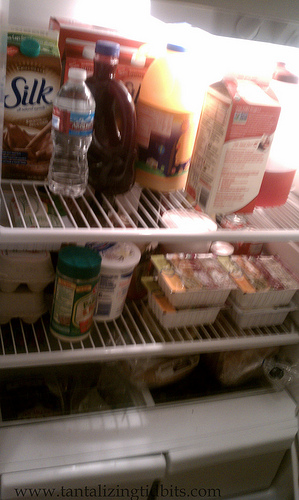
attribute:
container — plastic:
[101, 248, 146, 329]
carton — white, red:
[2, 23, 64, 185]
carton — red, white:
[165, 420, 298, 498]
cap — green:
[17, 36, 42, 57]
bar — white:
[1, 225, 297, 242]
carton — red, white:
[208, 74, 258, 217]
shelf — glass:
[1, 354, 276, 415]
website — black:
[12, 471, 246, 497]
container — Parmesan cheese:
[48, 245, 101, 342]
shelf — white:
[1, 169, 298, 244]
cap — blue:
[167, 44, 186, 50]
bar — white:
[2, 244, 288, 332]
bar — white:
[0, 332, 298, 367]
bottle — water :
[47, 64, 101, 201]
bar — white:
[5, 337, 273, 398]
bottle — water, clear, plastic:
[45, 65, 97, 198]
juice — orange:
[133, 38, 209, 196]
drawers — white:
[20, 406, 279, 489]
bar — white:
[0, 166, 297, 248]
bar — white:
[5, 165, 293, 362]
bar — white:
[0, 166, 296, 381]